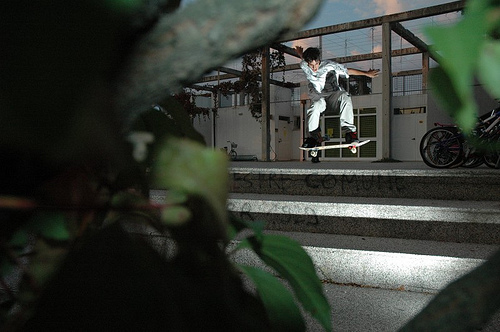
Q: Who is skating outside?
A: A person.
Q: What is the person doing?
A: Skateboarding.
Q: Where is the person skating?
A: On stairs.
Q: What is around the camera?
A: Leaves.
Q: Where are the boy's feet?
A: On the board.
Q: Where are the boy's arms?
A: Upward.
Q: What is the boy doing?
A: Skateboarding.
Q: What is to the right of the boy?
A: Bikes.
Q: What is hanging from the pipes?
A: Plant.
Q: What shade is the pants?
A: White.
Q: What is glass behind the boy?
A: Door.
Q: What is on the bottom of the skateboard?
A: Wheels.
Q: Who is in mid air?
A: The boy.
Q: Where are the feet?
A: On the skateboard.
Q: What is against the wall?
A: Bikes.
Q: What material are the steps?
A: Concrete.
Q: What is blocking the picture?
A: A plant.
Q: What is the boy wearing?
A: Clothes.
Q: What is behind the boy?
A: A building.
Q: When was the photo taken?
A: Daytime.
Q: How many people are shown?
A: One.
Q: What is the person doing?
A: Skateboarding.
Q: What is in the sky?
A: Clouds.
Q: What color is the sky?
A: Blue.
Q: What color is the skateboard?
A: White.